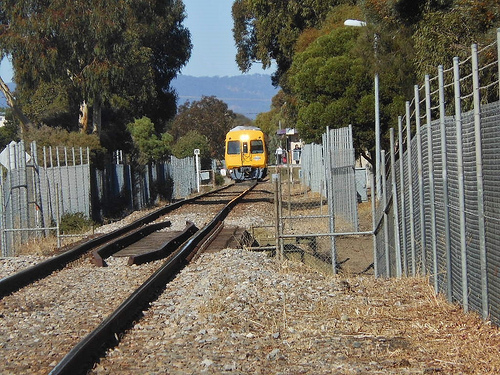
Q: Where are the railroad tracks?
A: In the ground.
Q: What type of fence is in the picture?
A: Chain link.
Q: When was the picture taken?
A: During the day.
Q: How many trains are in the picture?
A: One.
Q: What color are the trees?
A: Green.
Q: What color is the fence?
A: Silver.